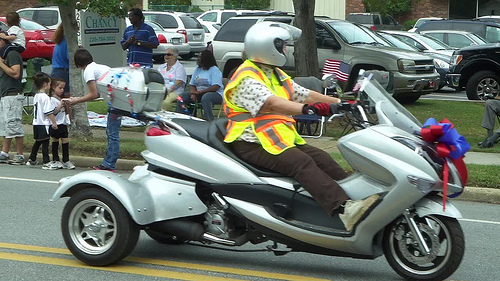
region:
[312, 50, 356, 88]
an american flag on the sidewalk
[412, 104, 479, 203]
a red and blue ribbon on the vehicle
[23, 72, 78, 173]
kids dressed in uniforms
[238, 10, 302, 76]
a silver motorcycle helmet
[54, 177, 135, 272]
a black rubber tire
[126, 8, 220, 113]
spectators sitting on the curb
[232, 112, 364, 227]
brown pants on a lady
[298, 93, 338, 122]
red riding gloves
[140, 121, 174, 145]
red taillight on the vehicle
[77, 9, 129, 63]
business sign on the curb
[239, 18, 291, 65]
the helmet is silver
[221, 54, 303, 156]
the vest is yellow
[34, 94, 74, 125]
the shirt is white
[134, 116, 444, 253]
the bike is silver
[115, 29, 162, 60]
the shirt is blue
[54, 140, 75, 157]
the socks are black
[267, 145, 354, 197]
the pants are brown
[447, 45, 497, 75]
the truck is black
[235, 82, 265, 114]
the shirt is spotted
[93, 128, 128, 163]
the jeans are blue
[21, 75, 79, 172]
two children on the side of the street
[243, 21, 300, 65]
a silver helmet on a persons head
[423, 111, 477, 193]
red and blue bow on the front of a tryc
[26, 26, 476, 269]
silver tryc in a parade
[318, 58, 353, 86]
American flag on the back of a chair on the side of the road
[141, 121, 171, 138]
taillight on the back of the 3 wheeler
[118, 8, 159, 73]
man standing in the grass at the side of the road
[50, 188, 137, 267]
wheel at the back of the tryc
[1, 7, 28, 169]
father holding child on the side of the road watching the parade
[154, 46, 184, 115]
woman sitting on a chair on the side of the street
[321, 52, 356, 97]
American flag on display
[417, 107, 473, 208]
Blue and red bow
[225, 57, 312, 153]
Yellow safety vest with orange and brown reflective material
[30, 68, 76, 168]
Two children in white and black uniforms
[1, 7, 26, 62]
Young child on father's shoulders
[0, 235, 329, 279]
Double yellow line on street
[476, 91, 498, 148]
Leg of man visible on right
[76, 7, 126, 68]
White, blue and green "Chancy" sign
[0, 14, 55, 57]
Red car on left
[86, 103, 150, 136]
Blanket on ground under "Chancy"sign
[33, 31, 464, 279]
a man on a motorbike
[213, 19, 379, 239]
this is a person in the picture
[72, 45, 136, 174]
this is a person in the picture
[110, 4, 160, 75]
this is a person in the picture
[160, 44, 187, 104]
this is a person in the picture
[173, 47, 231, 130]
this is a person in the picture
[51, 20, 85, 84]
this is a person in the picture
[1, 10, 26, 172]
this is a person in the picture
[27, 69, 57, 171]
this is a child in the picture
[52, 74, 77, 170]
this is a child in the picture